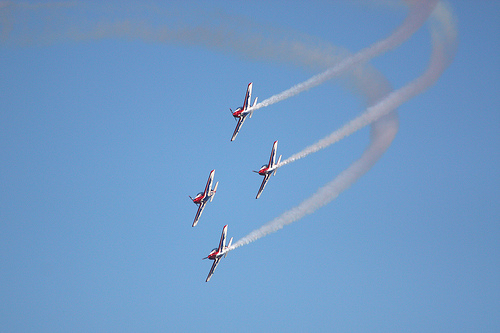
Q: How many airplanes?
A: Four.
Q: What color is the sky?
A: Blue.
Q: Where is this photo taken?
A: An airshow.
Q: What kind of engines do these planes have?
A: Propeller driven engine.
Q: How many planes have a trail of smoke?
A: Three.